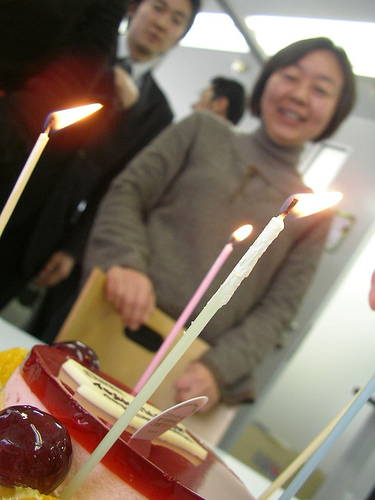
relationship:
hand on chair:
[109, 269, 159, 327] [77, 298, 172, 386]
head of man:
[135, 16, 223, 62] [123, 17, 162, 148]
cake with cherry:
[19, 374, 219, 500] [6, 410, 67, 475]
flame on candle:
[39, 98, 132, 153] [206, 245, 286, 358]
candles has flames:
[227, 178, 349, 250] [155, 140, 370, 242]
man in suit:
[123, 17, 162, 148] [87, 62, 166, 164]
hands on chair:
[109, 270, 249, 423] [77, 298, 172, 386]